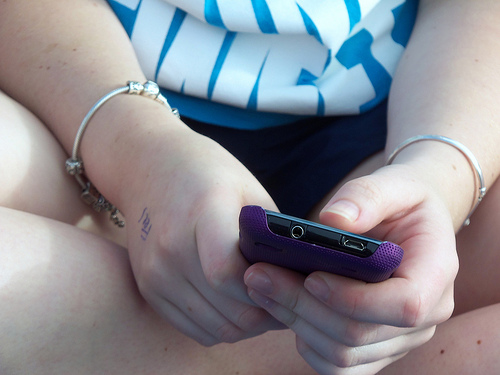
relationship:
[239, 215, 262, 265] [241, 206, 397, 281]
cover on a phone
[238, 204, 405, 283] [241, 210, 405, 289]
cell phone with purple cover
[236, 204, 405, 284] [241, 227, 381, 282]
cell phone with cover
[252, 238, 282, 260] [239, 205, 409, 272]
cover with phone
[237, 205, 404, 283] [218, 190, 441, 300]
purple cover with cell phone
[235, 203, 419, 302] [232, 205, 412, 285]
purple cover on cellphone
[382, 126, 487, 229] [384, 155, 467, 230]
bracelet on wrist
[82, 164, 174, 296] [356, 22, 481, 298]
tattoo on hand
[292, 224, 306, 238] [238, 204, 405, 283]
earphone jack on cell phone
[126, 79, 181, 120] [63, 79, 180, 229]
charms on bracelet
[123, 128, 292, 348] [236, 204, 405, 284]
hand on cell phone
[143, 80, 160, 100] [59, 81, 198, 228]
bead on bracelet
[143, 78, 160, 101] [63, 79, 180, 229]
bead on bracelet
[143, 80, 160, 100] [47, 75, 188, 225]
bead on bracelet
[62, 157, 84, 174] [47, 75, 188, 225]
bead on bracelet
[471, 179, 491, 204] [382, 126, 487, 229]
bead on bracelet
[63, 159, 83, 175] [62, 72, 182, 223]
bead on braclet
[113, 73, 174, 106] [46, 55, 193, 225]
beads on bracelet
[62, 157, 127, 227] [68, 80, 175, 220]
beads on bracelet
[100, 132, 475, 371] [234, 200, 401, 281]
hands on phone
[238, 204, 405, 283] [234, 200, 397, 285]
cell phone in purple case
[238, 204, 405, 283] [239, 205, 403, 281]
cell phone in purple case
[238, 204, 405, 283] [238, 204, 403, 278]
cell phone in case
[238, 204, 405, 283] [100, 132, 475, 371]
cell phone in hands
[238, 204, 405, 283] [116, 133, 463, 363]
cell phone in hands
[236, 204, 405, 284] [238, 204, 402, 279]
cell phone with a cover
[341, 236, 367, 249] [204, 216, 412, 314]
power input on a cellphone